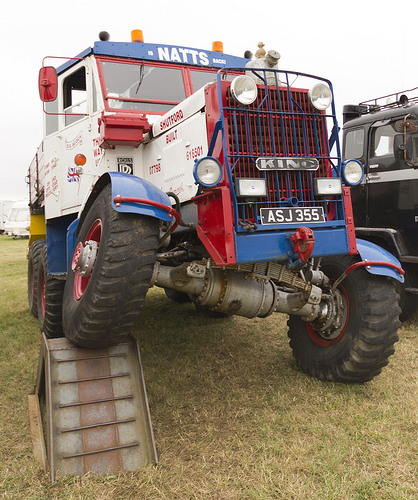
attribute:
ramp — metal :
[24, 321, 163, 489]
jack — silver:
[28, 330, 159, 485]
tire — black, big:
[62, 181, 159, 351]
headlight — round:
[231, 76, 258, 105]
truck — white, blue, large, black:
[28, 29, 405, 387]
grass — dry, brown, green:
[1, 233, 417, 499]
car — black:
[343, 104, 418, 290]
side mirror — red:
[39, 66, 57, 102]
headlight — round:
[309, 82, 333, 110]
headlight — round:
[195, 159, 223, 186]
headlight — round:
[344, 160, 363, 187]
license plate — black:
[259, 206, 327, 225]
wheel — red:
[72, 218, 104, 298]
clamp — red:
[290, 226, 314, 259]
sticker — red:
[159, 110, 184, 131]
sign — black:
[257, 156, 320, 171]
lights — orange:
[131, 30, 223, 53]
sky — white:
[1, 0, 418, 198]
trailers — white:
[0, 201, 32, 240]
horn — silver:
[364, 95, 409, 113]